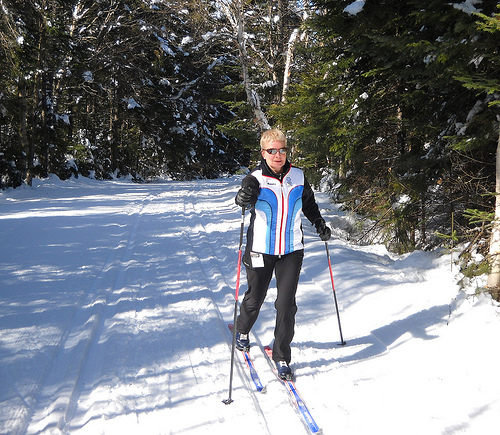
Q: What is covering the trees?
A: Snow.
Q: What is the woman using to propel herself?
A: Ski poles.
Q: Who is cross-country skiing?
A: The woman.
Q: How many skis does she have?
A: Two.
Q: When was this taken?
A: During the day.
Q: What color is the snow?
A: White.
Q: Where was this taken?
A: In a forest.